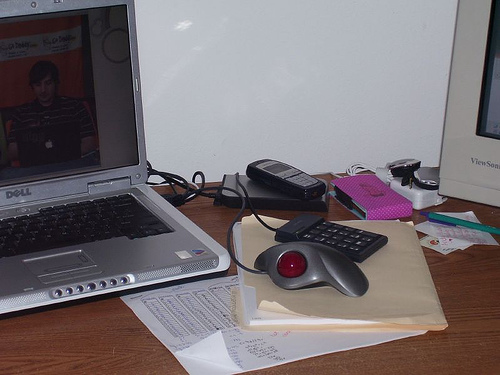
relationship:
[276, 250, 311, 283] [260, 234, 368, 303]
ball on mouse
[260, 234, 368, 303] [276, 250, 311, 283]
mouse has ball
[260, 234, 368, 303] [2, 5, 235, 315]
mouse of computer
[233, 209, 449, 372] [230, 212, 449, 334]
file folder as file folder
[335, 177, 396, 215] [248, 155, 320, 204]
case for phone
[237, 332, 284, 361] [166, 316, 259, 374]
scribble on paper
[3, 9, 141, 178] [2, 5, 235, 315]
monitor of laptop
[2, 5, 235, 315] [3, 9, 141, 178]
laptop has monitor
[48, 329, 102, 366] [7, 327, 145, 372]
grain of wood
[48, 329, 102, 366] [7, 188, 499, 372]
grain of desk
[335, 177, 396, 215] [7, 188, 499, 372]
case on desk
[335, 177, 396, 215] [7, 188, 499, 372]
case laying on desk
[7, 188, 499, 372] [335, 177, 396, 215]
desk with case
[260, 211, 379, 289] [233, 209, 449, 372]
objects on folder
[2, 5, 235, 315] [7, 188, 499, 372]
laptop on desk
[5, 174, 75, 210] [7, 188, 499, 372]
dell on desk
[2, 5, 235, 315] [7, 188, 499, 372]
laptop sitting on desk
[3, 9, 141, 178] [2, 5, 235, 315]
monitor of computer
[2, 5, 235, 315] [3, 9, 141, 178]
computer has monitor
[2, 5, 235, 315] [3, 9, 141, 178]
computer with monitor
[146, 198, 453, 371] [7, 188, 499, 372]
paperwork on desk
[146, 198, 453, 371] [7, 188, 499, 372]
paperwork laying on desk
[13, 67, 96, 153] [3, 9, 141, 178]
man on screen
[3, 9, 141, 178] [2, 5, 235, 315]
screen of computer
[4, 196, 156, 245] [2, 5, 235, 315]
keyboard of computer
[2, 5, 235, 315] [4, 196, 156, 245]
computer has keyboard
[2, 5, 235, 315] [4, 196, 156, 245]
computer with keyboard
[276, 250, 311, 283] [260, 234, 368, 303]
ball in mouse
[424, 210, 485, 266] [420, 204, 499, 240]
papers under pen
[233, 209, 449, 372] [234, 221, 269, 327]
folder of papers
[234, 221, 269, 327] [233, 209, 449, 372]
papers in folder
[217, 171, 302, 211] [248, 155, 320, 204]
hard drive with phone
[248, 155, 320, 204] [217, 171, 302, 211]
phone on hard drive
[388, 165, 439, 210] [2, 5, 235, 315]
charger for computer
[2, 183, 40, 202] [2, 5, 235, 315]
dell of computer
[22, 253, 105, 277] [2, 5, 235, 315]
trackpad of laptop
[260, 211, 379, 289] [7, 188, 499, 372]
objects on table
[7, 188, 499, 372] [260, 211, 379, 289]
table of objects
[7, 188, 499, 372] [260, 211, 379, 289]
table with objects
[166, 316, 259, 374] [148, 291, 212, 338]
paper with columns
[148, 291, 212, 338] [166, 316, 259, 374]
columns on paper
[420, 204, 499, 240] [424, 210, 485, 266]
pen on papers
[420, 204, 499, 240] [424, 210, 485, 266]
pen resting on papers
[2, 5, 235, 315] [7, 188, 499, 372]
laptop on table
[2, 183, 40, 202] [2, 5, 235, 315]
dell of laptop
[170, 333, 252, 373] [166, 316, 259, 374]
edge of paper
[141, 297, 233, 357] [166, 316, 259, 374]
piece of paper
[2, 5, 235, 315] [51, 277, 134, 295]
laptop has buttons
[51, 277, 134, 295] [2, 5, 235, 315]
buttons on laptop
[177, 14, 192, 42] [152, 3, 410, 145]
spot on wall